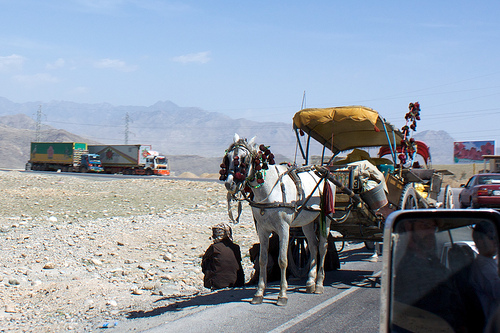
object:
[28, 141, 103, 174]
truck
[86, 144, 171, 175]
truck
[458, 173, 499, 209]
car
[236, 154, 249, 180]
blinder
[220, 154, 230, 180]
blinder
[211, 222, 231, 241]
rag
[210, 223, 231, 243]
head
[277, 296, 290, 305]
hoof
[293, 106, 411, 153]
brown covering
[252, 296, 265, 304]
hoof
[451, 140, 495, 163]
billboard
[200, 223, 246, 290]
people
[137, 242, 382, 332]
road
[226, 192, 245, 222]
straps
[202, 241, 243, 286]
shirt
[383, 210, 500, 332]
mirror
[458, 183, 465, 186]
mirror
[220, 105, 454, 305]
wagon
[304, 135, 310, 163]
pole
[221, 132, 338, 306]
horse